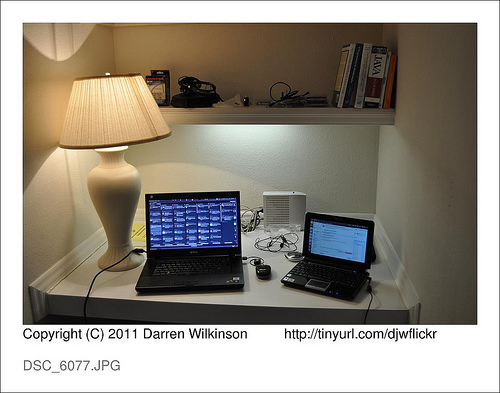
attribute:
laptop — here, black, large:
[133, 191, 245, 292]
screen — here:
[148, 197, 240, 249]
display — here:
[157, 203, 218, 242]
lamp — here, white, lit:
[62, 78, 174, 272]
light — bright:
[186, 122, 300, 163]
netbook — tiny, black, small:
[282, 212, 375, 303]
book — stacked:
[334, 42, 356, 111]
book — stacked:
[365, 44, 386, 106]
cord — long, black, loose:
[82, 247, 144, 326]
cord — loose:
[362, 274, 373, 325]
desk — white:
[45, 213, 413, 325]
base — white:
[88, 147, 146, 271]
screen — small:
[308, 219, 369, 262]